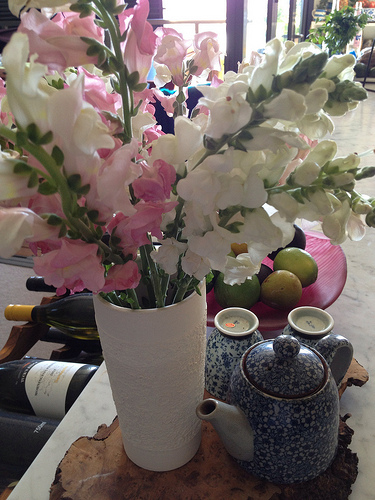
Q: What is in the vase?
A: Flowers.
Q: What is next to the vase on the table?
A: Teapot.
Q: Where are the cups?
A: On the table.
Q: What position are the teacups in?
A: Upside down.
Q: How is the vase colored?
A: White.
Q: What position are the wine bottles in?
A: Laying on their side.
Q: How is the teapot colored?
A: Blue and white.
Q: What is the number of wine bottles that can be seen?
A: Four.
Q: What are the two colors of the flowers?
A: White and pink.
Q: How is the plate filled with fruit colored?
A: Pink.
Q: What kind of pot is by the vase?
A: Teapot.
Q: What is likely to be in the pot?
A: Tea.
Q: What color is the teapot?
A: Blue and white.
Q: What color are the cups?
A: Blue and white.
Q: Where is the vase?
A: On the wood slab.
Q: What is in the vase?
A: Flowers.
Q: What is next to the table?
A: Wine.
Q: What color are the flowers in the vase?
A: Pink.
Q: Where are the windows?
A: In the room.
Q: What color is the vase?
A: White.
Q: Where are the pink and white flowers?
A: In the vase.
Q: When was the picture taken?
A: In the daytime.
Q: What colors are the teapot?
A: Blue and white.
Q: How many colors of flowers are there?
A: 2.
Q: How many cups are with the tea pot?
A: 2.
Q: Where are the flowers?
A: In a vase.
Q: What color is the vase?
A: White.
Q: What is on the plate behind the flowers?
A: Fruit.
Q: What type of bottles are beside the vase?
A: Wine bottles.